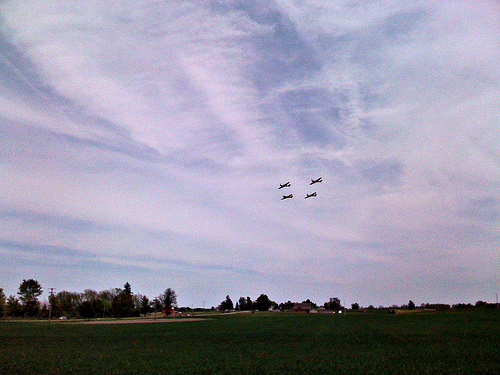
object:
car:
[59, 316, 67, 320]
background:
[0, 290, 500, 375]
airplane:
[278, 181, 292, 189]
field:
[3, 277, 499, 375]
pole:
[49, 288, 53, 323]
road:
[5, 318, 212, 323]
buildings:
[290, 302, 325, 314]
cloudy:
[288, 123, 340, 149]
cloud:
[142, 178, 279, 226]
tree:
[153, 287, 178, 315]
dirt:
[74, 317, 208, 322]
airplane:
[309, 177, 322, 186]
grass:
[248, 350, 285, 358]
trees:
[76, 282, 151, 319]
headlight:
[59, 317, 61, 319]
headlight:
[60, 317, 63, 319]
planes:
[305, 191, 318, 198]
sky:
[6, 14, 76, 82]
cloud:
[17, 30, 121, 113]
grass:
[395, 324, 429, 357]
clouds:
[340, 0, 500, 135]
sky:
[339, 0, 499, 97]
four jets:
[278, 177, 323, 200]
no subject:
[296, 200, 322, 210]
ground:
[0, 305, 500, 375]